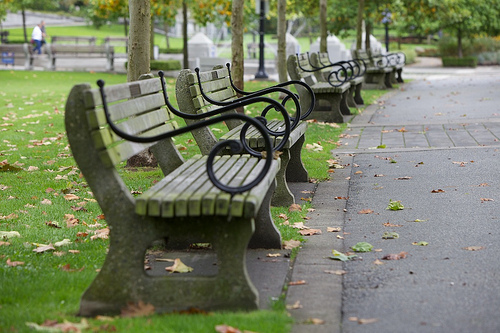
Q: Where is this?
A: This is at the park.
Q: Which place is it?
A: It is a park.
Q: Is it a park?
A: Yes, it is a park.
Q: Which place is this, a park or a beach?
A: It is a park.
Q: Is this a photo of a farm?
A: No, the picture is showing a park.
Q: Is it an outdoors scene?
A: Yes, it is outdoors.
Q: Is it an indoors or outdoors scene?
A: It is outdoors.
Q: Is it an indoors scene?
A: No, it is outdoors.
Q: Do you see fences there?
A: No, there are no fences.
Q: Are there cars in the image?
A: No, there are no cars.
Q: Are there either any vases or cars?
A: No, there are no cars or vases.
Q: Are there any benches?
A: Yes, there is a bench.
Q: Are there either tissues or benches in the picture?
A: Yes, there is a bench.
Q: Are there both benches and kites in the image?
A: No, there is a bench but no kites.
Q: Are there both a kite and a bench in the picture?
A: No, there is a bench but no kites.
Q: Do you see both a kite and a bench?
A: No, there is a bench but no kites.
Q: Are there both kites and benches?
A: No, there is a bench but no kites.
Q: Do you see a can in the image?
A: No, there are no cans.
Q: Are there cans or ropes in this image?
A: No, there are no cans or ropes.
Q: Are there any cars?
A: No, there are no cars.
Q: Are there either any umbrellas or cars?
A: No, there are no cars or umbrellas.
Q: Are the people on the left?
A: Yes, the people are on the left of the image.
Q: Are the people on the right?
A: No, the people are on the left of the image.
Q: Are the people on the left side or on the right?
A: The people are on the left of the image.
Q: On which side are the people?
A: The people are on the left of the image.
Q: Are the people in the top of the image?
A: Yes, the people are in the top of the image.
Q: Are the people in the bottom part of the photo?
A: No, the people are in the top of the image.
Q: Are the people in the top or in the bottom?
A: The people are in the top of the image.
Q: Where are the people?
A: The people are on the path.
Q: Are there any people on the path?
A: Yes, there are people on the path.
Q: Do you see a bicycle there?
A: No, there are no bicycles.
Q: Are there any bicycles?
A: No, there are no bicycles.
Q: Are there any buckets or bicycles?
A: No, there are no bicycles or buckets.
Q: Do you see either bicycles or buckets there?
A: No, there are no bicycles or buckets.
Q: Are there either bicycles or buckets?
A: No, there are no bicycles or buckets.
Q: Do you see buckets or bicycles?
A: No, there are no bicycles or buckets.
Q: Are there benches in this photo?
A: Yes, there is a bench.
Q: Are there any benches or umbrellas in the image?
A: Yes, there is a bench.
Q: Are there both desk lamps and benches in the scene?
A: No, there is a bench but no desk lamps.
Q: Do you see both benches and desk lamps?
A: No, there is a bench but no desk lamps.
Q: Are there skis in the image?
A: No, there are no skis.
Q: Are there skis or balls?
A: No, there are no skis or balls.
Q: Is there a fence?
A: No, there are no fences.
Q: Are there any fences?
A: No, there are no fences.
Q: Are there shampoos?
A: No, there are no shampoos.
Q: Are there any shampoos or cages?
A: No, there are no shampoos or cages.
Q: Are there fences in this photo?
A: No, there are no fences.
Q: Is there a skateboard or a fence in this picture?
A: No, there are no fences or skateboards.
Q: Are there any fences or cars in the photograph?
A: No, there are no fences or cars.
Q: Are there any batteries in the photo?
A: No, there are no batteries.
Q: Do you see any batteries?
A: No, there are no batteries.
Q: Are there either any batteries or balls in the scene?
A: No, there are no batteries or balls.